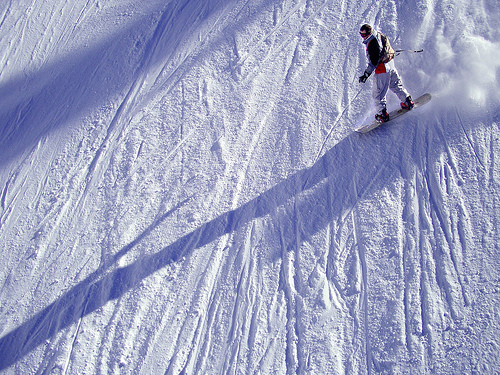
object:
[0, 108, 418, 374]
shadow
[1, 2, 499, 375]
snow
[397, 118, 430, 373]
trail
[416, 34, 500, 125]
dust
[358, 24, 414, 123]
snowboarder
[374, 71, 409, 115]
pants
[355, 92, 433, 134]
snowboard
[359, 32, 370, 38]
goggles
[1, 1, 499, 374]
hill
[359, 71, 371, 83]
left hand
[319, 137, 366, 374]
trail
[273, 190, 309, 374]
trail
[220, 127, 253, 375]
trail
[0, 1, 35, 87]
trail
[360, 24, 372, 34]
hair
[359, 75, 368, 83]
glove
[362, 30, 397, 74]
coat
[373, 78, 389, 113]
leg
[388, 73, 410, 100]
leg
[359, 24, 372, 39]
head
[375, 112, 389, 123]
foot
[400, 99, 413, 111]
foot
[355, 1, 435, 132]
trail